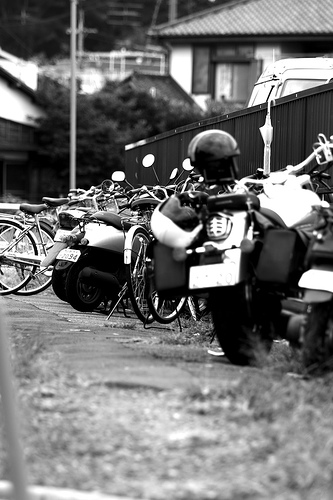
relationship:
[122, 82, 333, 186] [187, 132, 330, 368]
fence on bike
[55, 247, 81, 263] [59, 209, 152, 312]
license on motorcycle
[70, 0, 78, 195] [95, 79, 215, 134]
pole on bush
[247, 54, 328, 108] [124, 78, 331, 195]
van on fence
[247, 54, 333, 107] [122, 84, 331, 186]
van on fence